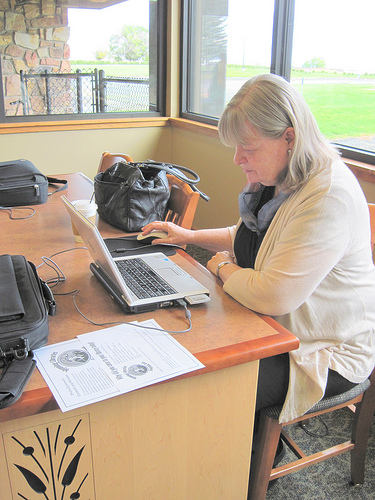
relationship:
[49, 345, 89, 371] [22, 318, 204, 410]
writing on paper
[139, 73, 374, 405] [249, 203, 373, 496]
woman sitting on chair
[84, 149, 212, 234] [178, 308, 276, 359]
handbag on table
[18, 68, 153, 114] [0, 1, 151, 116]
black fencing outside of window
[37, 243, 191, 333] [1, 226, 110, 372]
cords laying on desk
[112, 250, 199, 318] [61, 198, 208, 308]
keyboard on laptop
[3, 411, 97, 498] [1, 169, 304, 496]
pattern on desk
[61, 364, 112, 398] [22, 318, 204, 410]
writing on paper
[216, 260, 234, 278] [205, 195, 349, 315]
watch on arm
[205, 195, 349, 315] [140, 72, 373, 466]
arm of woman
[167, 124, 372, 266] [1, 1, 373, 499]
wall on building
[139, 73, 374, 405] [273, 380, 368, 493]
woman sitting in chair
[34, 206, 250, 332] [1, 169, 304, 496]
laptop on desk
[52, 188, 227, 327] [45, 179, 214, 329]
keyboard on laptop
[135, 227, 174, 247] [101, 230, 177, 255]
mouse on mousepad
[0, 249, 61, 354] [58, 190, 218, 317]
bag for laptop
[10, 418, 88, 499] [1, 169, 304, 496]
stencil on desk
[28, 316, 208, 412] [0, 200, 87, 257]
papers on desk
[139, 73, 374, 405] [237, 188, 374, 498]
woman on chair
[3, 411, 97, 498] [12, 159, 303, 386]
pattern on desk